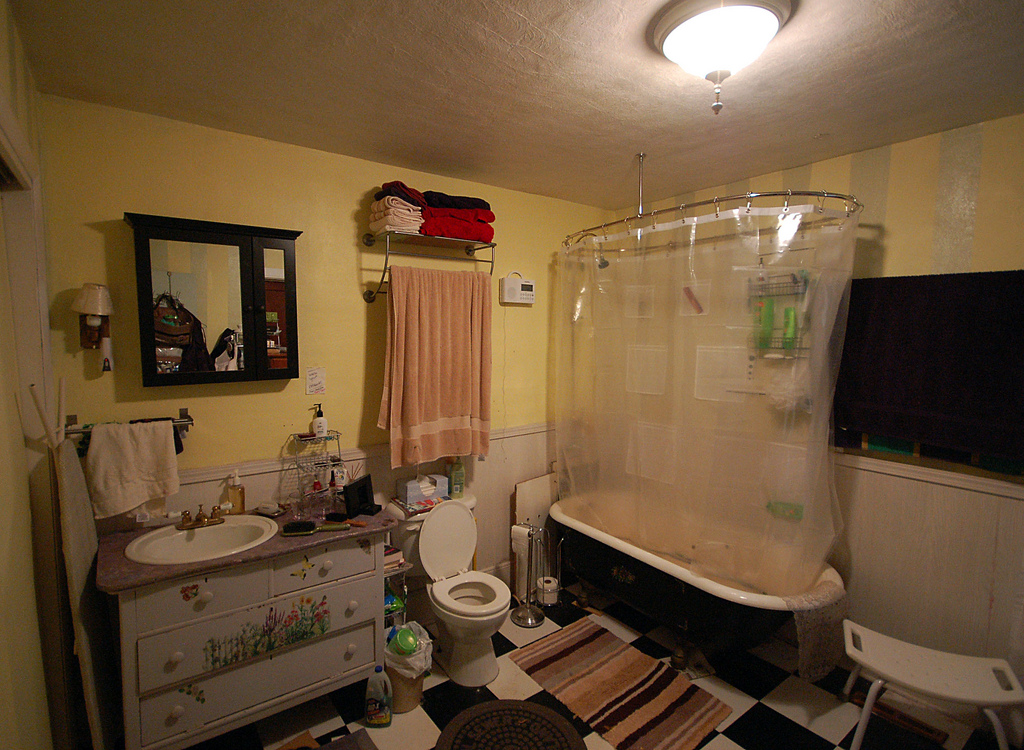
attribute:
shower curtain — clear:
[550, 184, 865, 595]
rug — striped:
[513, 609, 730, 745]